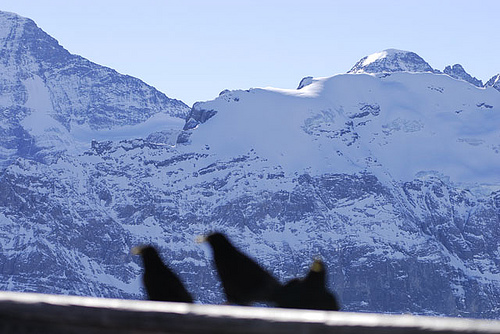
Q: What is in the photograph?
A: Birds.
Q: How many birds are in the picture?
A: Three.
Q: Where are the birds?
A: On a window ledge.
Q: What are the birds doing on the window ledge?
A: Standing.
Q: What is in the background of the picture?
A: Mountain.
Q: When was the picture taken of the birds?
A: Winter.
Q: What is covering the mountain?
A: Snow.